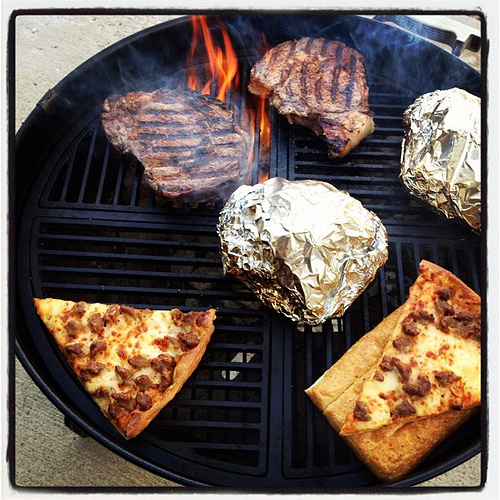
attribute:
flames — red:
[187, 14, 272, 185]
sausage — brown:
[180, 327, 201, 346]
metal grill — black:
[255, 134, 333, 185]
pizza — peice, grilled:
[31, 293, 219, 443]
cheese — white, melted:
[119, 325, 164, 347]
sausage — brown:
[171, 327, 201, 351]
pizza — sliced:
[338, 260, 485, 437]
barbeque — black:
[17, 14, 484, 486]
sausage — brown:
[403, 381, 435, 395]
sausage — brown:
[388, 400, 417, 417]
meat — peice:
[87, 88, 277, 199]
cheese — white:
[152, 311, 168, 338]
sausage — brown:
[375, 355, 418, 377]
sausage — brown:
[124, 351, 153, 371]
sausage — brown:
[87, 344, 106, 362]